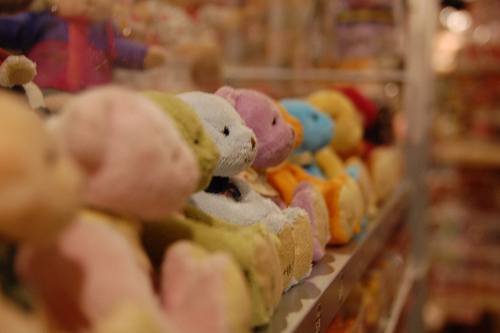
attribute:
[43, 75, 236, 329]
bear — pink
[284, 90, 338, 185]
teddy bear — blue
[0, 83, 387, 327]
animals — stuffed, various colors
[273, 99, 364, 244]
bear — orange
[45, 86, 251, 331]
stuffed animal — soft, furry, light pink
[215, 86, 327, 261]
stuffed toy — purple, brown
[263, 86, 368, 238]
teddy bear — bright, blue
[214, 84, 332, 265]
bear — teddy, pink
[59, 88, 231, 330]
teddy bear — white, blue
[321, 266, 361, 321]
tag — price, black, white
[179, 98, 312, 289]
animal — white, stuffed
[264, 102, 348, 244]
teddy bear — orange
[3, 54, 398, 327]
teddy bears — small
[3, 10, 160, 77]
animal — stuffed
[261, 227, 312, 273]
foot — teddy bear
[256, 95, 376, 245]
stuffed animal — carrot colored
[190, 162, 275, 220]
tie — black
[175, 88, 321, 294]
teddy bear — pink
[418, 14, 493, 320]
area — blurred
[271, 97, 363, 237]
teddy bear — blue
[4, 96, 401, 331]
toys — stuffed, cuddly, colorful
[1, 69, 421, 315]
teddy bears — different colors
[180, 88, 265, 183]
bear face — white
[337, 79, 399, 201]
teddy bear — red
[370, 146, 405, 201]
feet — brown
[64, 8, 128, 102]
suspenders — pink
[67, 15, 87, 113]
tie — pink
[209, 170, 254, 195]
scarf — blue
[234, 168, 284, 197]
jacket — purple, pink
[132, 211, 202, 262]
jacket — purple, pink